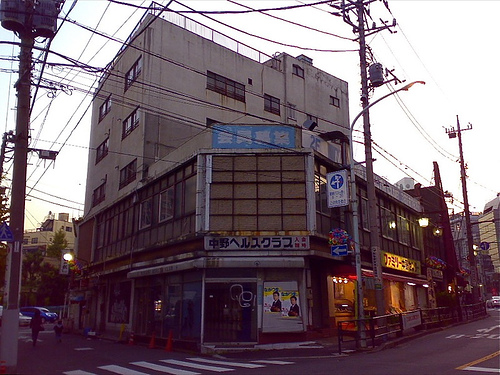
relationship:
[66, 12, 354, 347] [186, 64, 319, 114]
building has windows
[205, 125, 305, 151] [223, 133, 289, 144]
sign has writing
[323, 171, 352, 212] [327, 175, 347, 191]
street sign has circle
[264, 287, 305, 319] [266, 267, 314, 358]
poster on wall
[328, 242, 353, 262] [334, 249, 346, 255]
sign with arrow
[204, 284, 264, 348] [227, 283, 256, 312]
door has graffiti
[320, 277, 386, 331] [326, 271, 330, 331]
store in corner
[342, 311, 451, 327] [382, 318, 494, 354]
passage on street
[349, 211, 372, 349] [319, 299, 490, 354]
pole on passage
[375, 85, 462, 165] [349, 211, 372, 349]
wires on pole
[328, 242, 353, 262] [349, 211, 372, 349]
sign on pole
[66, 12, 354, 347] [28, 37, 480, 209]
building in background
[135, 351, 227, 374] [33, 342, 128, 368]
lines in road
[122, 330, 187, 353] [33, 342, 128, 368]
cones on road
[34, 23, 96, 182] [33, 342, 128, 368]
wires above road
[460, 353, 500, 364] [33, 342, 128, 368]
line in road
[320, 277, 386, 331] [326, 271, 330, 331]
store on corner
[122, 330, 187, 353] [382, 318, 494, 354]
cones on street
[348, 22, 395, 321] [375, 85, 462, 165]
pole has wires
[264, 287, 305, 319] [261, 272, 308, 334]
poster on window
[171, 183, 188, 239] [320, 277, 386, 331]
window on store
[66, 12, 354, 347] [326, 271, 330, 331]
building in corner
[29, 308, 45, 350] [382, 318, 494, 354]
mom on street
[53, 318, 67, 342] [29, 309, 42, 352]
child with mom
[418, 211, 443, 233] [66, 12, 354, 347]
lights on building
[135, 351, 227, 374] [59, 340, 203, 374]
lines on pavement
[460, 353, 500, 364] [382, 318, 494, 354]
line on street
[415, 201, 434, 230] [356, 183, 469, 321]
lamp hanging from building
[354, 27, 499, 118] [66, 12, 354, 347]
sky above building